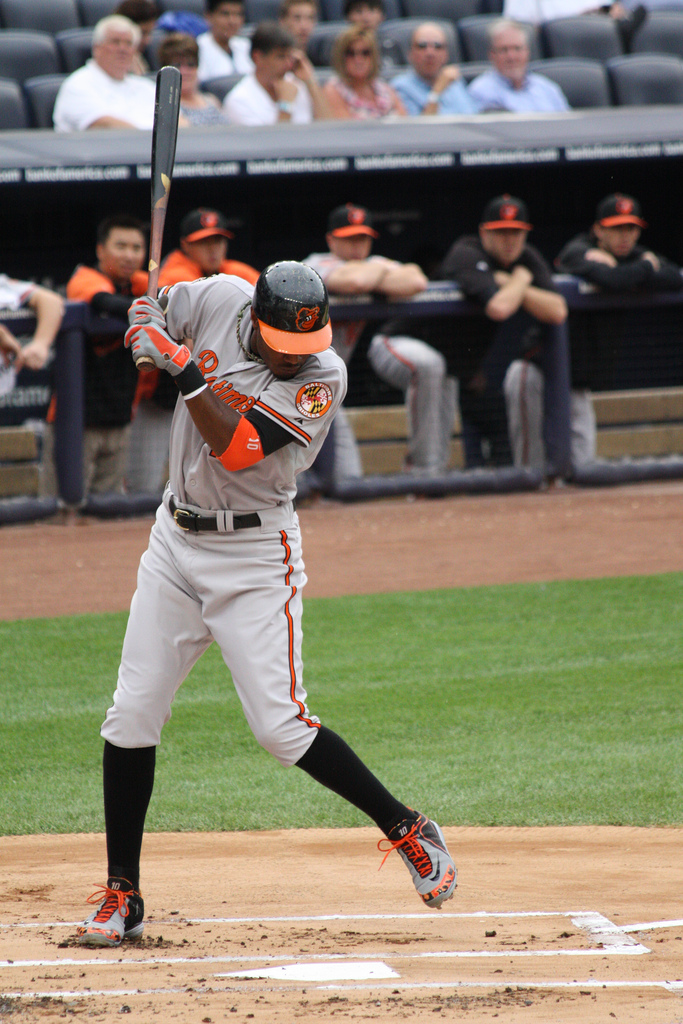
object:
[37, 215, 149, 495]
player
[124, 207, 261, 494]
player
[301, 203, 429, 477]
player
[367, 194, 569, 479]
player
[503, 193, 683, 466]
player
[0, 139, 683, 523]
dugout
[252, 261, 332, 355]
helmet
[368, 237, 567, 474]
uniform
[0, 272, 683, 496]
fence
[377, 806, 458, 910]
cleat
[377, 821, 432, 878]
laces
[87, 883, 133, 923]
laces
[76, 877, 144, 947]
cleat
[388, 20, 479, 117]
man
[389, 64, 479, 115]
shirt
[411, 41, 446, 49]
sunglasses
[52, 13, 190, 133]
man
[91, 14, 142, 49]
hair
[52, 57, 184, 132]
shirt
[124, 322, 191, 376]
glove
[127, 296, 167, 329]
glove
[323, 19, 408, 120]
woman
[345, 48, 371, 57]
sunglasses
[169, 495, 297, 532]
belt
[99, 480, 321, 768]
pants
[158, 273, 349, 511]
shirt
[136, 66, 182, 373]
bat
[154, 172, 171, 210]
star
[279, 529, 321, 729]
stripe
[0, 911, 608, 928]
line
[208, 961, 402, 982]
plate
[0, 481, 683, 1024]
ground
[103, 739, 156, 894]
sock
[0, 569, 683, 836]
grass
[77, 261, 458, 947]
man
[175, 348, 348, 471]
arm